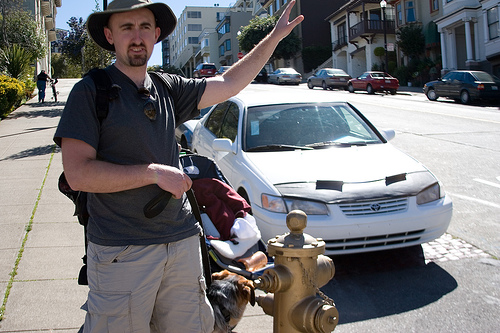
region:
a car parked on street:
[185, 85, 452, 271]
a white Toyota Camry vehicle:
[189, 88, 455, 264]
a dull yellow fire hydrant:
[254, 210, 338, 331]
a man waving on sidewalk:
[52, 0, 302, 330]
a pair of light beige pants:
[87, 235, 213, 330]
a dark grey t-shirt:
[53, 63, 206, 244]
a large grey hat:
[86, 0, 176, 55]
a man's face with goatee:
[103, 10, 163, 71]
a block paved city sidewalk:
[0, 76, 277, 331]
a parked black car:
[422, 65, 498, 105]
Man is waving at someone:
[58, 3, 389, 160]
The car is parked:
[194, 81, 474, 281]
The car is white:
[187, 74, 464, 246]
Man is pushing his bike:
[11, 57, 61, 112]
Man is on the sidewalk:
[24, 55, 59, 115]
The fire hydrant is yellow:
[247, 200, 372, 329]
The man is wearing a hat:
[68, 0, 194, 65]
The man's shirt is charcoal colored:
[56, 58, 225, 247]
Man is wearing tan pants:
[61, 233, 229, 332]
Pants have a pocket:
[68, 268, 150, 330]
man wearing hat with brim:
[46, 0, 210, 62]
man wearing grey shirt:
[39, 52, 233, 272]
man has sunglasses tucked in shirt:
[113, 53, 170, 150]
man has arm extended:
[154, 0, 309, 141]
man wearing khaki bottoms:
[60, 215, 245, 328]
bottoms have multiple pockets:
[65, 221, 240, 329]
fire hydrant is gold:
[227, 196, 362, 331]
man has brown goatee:
[124, 35, 156, 73]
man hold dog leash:
[152, 165, 267, 327]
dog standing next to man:
[202, 241, 269, 326]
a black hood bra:
[270, 168, 440, 207]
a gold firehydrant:
[255, 208, 346, 331]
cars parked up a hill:
[191, 55, 498, 113]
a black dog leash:
[141, 173, 216, 305]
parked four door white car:
[187, 85, 454, 260]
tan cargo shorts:
[80, 238, 222, 329]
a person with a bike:
[33, 67, 63, 109]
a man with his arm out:
[50, 0, 304, 329]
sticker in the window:
[245, 115, 262, 137]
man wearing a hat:
[77, 1, 182, 75]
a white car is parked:
[179, 62, 451, 300]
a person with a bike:
[18, 55, 70, 111]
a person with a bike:
[10, 35, 80, 105]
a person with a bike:
[13, 43, 98, 133]